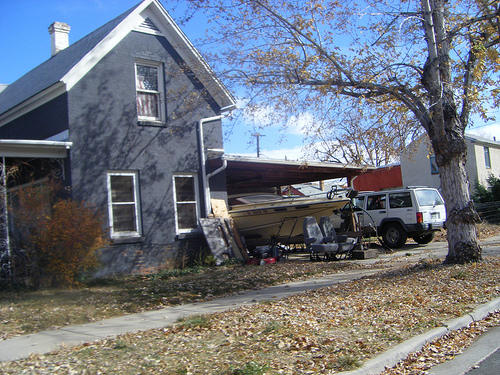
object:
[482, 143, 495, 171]
window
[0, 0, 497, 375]
outdoors scene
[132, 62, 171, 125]
window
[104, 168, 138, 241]
window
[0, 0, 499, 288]
building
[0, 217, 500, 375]
street